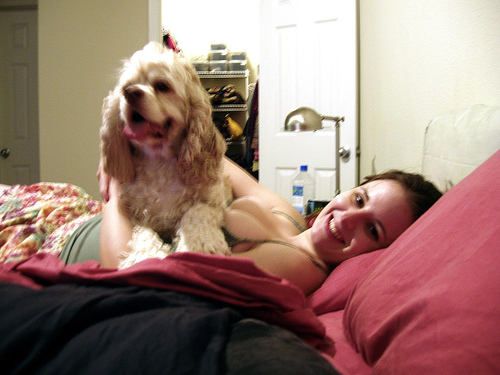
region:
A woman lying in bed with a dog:
[91, 35, 442, 270]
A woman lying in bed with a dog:
[95, 35, 447, 277]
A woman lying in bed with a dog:
[95, 36, 445, 296]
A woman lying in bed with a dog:
[93, 37, 444, 288]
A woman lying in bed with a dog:
[97, 33, 443, 300]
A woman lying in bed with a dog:
[95, 36, 447, 302]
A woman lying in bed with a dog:
[97, 37, 443, 292]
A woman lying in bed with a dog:
[85, 45, 450, 297]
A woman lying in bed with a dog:
[83, 35, 439, 296]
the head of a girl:
[304, 148, 441, 265]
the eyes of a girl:
[343, 167, 395, 257]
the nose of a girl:
[328, 198, 361, 246]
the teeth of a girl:
[308, 210, 344, 255]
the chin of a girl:
[306, 213, 333, 264]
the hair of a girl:
[362, 156, 487, 224]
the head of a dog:
[78, 58, 219, 152]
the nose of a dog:
[110, 77, 155, 127]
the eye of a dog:
[138, 60, 185, 105]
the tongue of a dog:
[104, 113, 198, 188]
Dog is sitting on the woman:
[93, 40, 230, 264]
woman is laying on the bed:
[63, 100, 437, 290]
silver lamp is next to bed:
[281, 102, 348, 192]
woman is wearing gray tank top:
[63, 196, 319, 273]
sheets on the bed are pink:
[9, 173, 496, 366]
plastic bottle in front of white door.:
[292, 160, 318, 210]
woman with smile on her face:
[300, 179, 406, 261]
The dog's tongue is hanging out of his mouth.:
[118, 112, 160, 139]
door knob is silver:
[336, 147, 351, 158]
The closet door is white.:
[259, 8, 360, 202]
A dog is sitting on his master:
[10, 18, 482, 353]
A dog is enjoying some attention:
[0, 17, 496, 337]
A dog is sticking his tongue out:
[11, 20, 496, 343]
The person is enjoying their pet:
[18, 31, 471, 347]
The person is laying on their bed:
[6, 21, 481, 356]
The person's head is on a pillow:
[10, 25, 470, 346]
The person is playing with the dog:
[5, 16, 490, 356]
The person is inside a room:
[3, 10, 498, 356]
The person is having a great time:
[10, 28, 486, 353]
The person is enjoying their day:
[35, 30, 479, 341]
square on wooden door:
[11, 23, 28, 50]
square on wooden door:
[16, 60, 30, 143]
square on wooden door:
[15, 162, 31, 185]